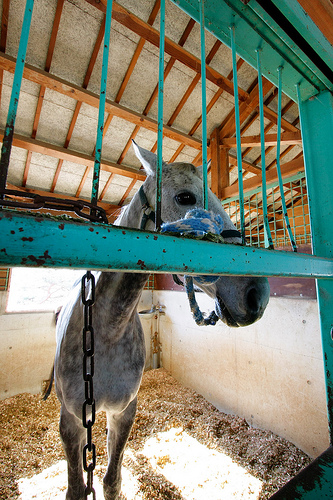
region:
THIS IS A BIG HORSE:
[25, 137, 287, 496]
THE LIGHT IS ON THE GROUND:
[6, 421, 269, 497]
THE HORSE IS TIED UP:
[150, 202, 237, 339]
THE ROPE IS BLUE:
[150, 202, 234, 341]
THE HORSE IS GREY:
[22, 127, 279, 497]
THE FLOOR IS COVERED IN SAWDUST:
[3, 356, 301, 496]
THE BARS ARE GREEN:
[0, 0, 330, 498]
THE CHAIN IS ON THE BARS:
[65, 258, 112, 497]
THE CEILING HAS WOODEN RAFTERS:
[0, 0, 322, 214]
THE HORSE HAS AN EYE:
[167, 182, 207, 221]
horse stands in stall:
[48, 139, 271, 499]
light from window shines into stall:
[5, 423, 263, 499]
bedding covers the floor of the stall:
[2, 364, 311, 499]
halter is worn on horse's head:
[135, 183, 242, 278]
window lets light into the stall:
[7, 264, 102, 316]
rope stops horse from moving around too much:
[157, 202, 235, 328]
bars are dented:
[252, 45, 298, 252]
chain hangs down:
[1, 188, 108, 499]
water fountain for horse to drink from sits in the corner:
[135, 301, 165, 368]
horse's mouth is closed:
[210, 289, 243, 328]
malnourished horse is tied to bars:
[50, 139, 271, 498]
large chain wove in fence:
[0, 188, 111, 499]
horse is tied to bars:
[161, 206, 224, 334]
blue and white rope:
[158, 199, 219, 328]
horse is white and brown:
[46, 139, 269, 498]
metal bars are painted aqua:
[0, 2, 331, 499]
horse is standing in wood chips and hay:
[0, 362, 313, 499]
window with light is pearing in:
[5, 267, 98, 316]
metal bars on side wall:
[215, 174, 313, 261]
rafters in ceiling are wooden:
[0, 2, 306, 241]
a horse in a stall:
[34, 131, 288, 487]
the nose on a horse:
[200, 277, 273, 330]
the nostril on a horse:
[241, 284, 261, 313]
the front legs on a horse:
[53, 407, 141, 497]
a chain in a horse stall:
[79, 268, 101, 498]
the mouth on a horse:
[214, 293, 241, 331]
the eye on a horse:
[171, 187, 199, 209]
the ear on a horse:
[128, 135, 157, 176]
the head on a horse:
[130, 140, 268, 330]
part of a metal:
[148, 172, 167, 207]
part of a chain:
[78, 434, 105, 477]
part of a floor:
[179, 429, 208, 474]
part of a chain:
[99, 464, 118, 495]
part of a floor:
[188, 454, 212, 494]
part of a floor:
[204, 446, 224, 478]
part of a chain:
[81, 424, 100, 451]